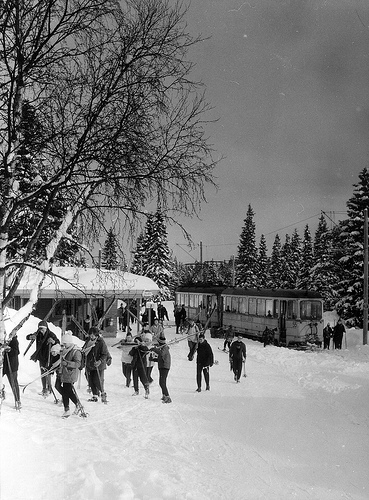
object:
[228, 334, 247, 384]
people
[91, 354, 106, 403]
skis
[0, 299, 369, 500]
snow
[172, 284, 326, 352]
train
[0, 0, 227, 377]
tree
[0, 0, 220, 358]
snow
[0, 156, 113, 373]
branches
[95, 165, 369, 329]
snow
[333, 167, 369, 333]
trees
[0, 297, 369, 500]
ground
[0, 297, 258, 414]
up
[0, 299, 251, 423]
equipment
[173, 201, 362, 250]
cables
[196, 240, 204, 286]
pole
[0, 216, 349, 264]
bundled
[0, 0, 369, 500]
weather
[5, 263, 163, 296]
snow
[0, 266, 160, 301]
roof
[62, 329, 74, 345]
hat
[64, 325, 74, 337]
pom pom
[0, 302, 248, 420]
group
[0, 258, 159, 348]
house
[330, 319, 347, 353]
person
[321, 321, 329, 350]
person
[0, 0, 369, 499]
background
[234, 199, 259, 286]
tree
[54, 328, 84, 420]
lady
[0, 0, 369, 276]
sky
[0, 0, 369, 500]
everything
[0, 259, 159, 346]
building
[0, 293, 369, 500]
hill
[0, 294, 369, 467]
ski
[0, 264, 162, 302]
top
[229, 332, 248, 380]
skiers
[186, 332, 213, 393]
man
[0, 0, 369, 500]
image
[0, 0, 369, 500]
day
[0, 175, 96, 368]
trunk